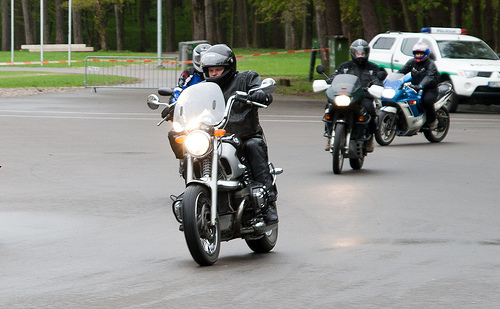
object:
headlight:
[182, 130, 211, 154]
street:
[2, 62, 497, 306]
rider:
[311, 38, 385, 173]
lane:
[1, 107, 497, 307]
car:
[367, 26, 497, 117]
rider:
[188, 41, 300, 194]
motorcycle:
[310, 64, 375, 171]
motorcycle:
[141, 80, 278, 263]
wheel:
[370, 102, 402, 148]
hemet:
[408, 33, 433, 63]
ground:
[452, 134, 477, 160]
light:
[182, 130, 214, 156]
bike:
[139, 61, 294, 281]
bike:
[381, 47, 460, 170]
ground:
[373, 143, 413, 184]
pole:
[157, 0, 163, 71]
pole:
[65, 0, 70, 67]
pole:
[39, 0, 43, 63]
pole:
[9, 0, 14, 63]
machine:
[309, 56, 387, 178]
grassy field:
[11, 34, 164, 85]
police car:
[364, 25, 499, 103]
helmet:
[194, 40, 241, 90]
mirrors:
[146, 81, 283, 111]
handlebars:
[146, 84, 283, 129]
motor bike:
[170, 177, 227, 265]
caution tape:
[18, 44, 323, 61]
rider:
[384, 37, 481, 144]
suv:
[365, 25, 497, 115]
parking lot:
[5, 99, 497, 307]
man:
[162, 42, 278, 221]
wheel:
[239, 193, 283, 253]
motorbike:
[144, 77, 282, 267]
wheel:
[344, 128, 376, 170]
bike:
[307, 50, 383, 177]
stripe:
[359, 60, 464, 82]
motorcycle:
[360, 37, 474, 155]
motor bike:
[374, 65, 457, 148]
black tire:
[177, 177, 227, 267]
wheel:
[178, 185, 213, 267]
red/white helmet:
[408, 36, 435, 63]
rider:
[393, 30, 447, 147]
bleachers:
[23, 25, 90, 64]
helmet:
[408, 34, 437, 58]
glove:
[244, 89, 275, 106]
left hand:
[239, 80, 268, 103]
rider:
[161, 38, 212, 226]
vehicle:
[363, 16, 484, 101]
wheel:
[178, 181, 227, 263]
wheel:
[236, 180, 280, 254]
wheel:
[324, 119, 348, 170]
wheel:
[374, 104, 401, 150]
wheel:
[421, 97, 452, 143]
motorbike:
[304, 70, 399, 186]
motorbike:
[370, 65, 459, 150]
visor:
[199, 51, 227, 70]